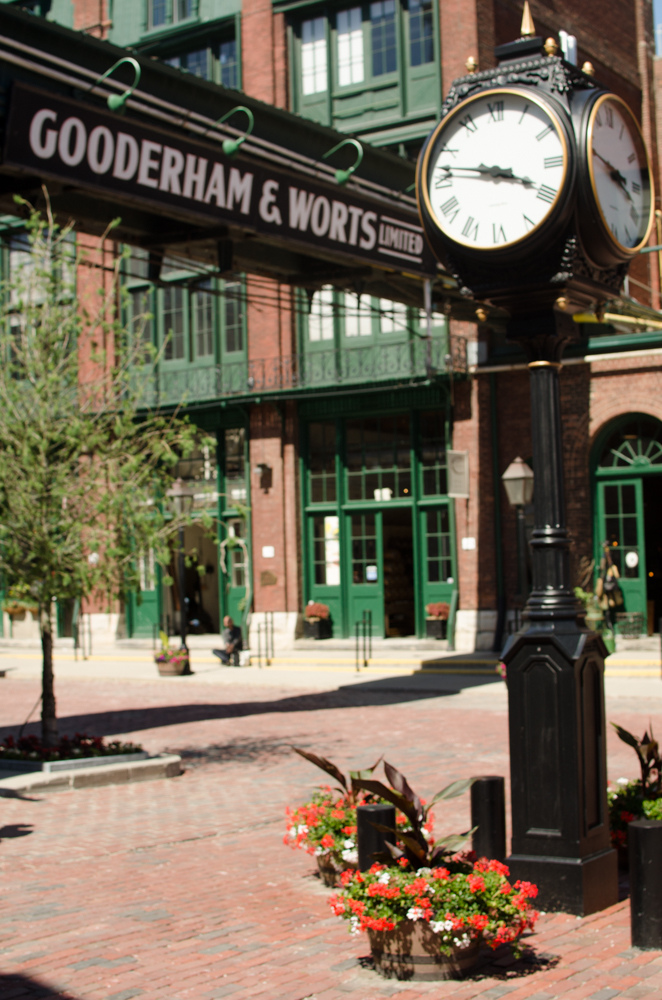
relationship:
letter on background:
[53, 107, 86, 178] [0, 0, 662, 672]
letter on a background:
[131, 129, 175, 198] [0, 0, 662, 672]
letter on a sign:
[153, 127, 189, 194] [0, 15, 456, 338]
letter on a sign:
[198, 154, 231, 209] [0, 44, 423, 294]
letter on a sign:
[227, 168, 259, 219] [12, 28, 414, 296]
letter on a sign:
[258, 173, 285, 230] [68, 26, 430, 294]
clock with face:
[403, 20, 625, 922] [415, 83, 571, 256]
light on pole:
[97, 89, 147, 127] [99, 54, 147, 85]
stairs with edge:
[77, 642, 492, 669] [78, 662, 458, 666]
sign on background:
[29, 108, 424, 263] [12, 39, 415, 271]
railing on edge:
[128, 331, 468, 405] [84, 381, 464, 409]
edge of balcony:
[84, 381, 464, 409] [105, 333, 463, 418]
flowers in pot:
[325, 851, 538, 953] [360, 918, 498, 984]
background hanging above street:
[0, 0, 662, 672] [110, 624, 499, 698]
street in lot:
[110, 624, 499, 698] [17, 677, 614, 981]